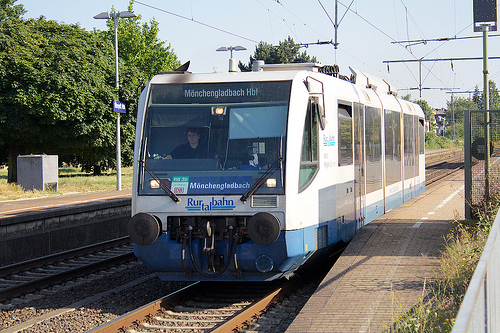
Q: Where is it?
A: This is at the sidewalk.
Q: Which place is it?
A: It is a sidewalk.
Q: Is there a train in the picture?
A: Yes, there is a train.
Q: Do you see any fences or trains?
A: Yes, there is a train.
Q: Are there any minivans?
A: No, there are no minivans.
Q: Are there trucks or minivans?
A: No, there are no minivans or trucks.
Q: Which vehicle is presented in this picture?
A: The vehicle is a train.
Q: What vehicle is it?
A: The vehicle is a train.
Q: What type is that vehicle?
A: This is a train.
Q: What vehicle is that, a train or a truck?
A: This is a train.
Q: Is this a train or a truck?
A: This is a train.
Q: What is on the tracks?
A: The train is on the tracks.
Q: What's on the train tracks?
A: The train is on the tracks.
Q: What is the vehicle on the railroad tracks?
A: The vehicle is a train.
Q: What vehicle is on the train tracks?
A: The vehicle is a train.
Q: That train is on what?
A: The train is on the train tracks.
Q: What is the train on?
A: The train is on the train tracks.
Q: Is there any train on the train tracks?
A: Yes, there is a train on the train tracks.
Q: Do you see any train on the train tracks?
A: Yes, there is a train on the train tracks.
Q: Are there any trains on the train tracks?
A: Yes, there is a train on the train tracks.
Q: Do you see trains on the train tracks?
A: Yes, there is a train on the train tracks.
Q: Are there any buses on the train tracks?
A: No, there is a train on the train tracks.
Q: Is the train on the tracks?
A: Yes, the train is on the tracks.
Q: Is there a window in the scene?
A: Yes, there is a window.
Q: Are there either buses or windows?
A: Yes, there is a window.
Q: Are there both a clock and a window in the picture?
A: No, there is a window but no clocks.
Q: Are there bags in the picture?
A: No, there are no bags.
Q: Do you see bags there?
A: No, there are no bags.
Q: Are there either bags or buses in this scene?
A: No, there are no bags or buses.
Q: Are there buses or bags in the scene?
A: No, there are no bags or buses.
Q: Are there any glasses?
A: No, there are no glasses.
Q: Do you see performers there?
A: No, there are no performers.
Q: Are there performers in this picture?
A: No, there are no performers.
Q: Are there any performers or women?
A: No, there are no performers or women.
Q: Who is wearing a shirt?
A: The man is wearing a shirt.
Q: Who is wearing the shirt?
A: The man is wearing a shirt.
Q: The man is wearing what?
A: The man is wearing a shirt.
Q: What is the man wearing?
A: The man is wearing a shirt.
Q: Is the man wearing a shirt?
A: Yes, the man is wearing a shirt.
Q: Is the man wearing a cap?
A: No, the man is wearing a shirt.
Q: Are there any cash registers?
A: No, there are no cash registers.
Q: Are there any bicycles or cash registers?
A: No, there are no cash registers or bicycles.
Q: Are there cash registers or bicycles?
A: No, there are no cash registers or bicycles.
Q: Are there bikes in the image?
A: No, there are no bikes.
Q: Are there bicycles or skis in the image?
A: No, there are no bicycles or skis.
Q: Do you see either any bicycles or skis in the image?
A: No, there are no bicycles or skis.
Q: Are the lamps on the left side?
A: Yes, the lamps are on the left of the image.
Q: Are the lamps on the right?
A: No, the lamps are on the left of the image.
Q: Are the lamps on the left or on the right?
A: The lamps are on the left of the image.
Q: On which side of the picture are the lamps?
A: The lamps are on the left of the image.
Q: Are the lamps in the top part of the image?
A: Yes, the lamps are in the top of the image.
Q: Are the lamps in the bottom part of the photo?
A: No, the lamps are in the top of the image.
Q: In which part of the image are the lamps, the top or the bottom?
A: The lamps are in the top of the image.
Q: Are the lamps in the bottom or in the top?
A: The lamps are in the top of the image.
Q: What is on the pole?
A: The lamps are on the pole.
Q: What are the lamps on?
A: The lamps are on the pole.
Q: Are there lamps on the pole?
A: Yes, there are lamps on the pole.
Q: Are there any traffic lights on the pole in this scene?
A: No, there are lamps on the pole.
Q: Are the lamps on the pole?
A: Yes, the lamps are on the pole.